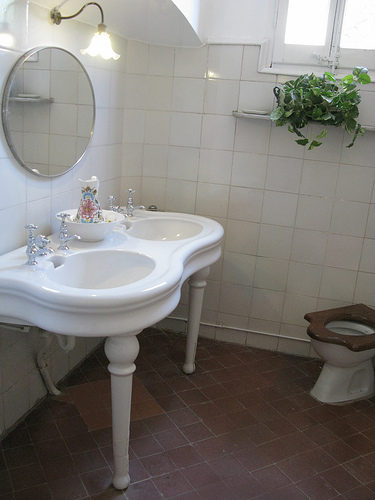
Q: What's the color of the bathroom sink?
A: White.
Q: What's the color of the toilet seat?
A: Brown.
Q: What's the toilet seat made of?
A: Wood.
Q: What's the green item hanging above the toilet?
A: Plant.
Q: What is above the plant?
A: Window.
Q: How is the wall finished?
A: Tile.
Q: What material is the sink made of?
A: Porcelain.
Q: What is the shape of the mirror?
A: Round.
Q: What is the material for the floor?
A: Brick.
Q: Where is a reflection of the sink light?
A: Left of sink light.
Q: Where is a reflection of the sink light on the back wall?
A: Left of the plant.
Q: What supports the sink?
A: Two legs.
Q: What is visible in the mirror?
A: Plant shelf.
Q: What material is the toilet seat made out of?
A: Wood.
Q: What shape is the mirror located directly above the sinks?
A: Circle.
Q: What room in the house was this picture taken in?
A: The bathroom.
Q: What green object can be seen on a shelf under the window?
A: A plant.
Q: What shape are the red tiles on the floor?
A: Square.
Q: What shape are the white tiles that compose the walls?
A: Square.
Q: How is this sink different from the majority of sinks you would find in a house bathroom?
A: There are two of them.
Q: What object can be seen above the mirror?
A: A light.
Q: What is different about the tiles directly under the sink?
A: They are a different color than the rest.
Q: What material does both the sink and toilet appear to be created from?
A: Porcelain.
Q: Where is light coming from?
A: A window.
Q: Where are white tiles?
A: On the wall.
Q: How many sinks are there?
A: Two.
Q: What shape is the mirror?
A: Round.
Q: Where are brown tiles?
A: On the floor.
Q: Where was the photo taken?
A: In a bathroom.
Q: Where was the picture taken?
A: At the entrance.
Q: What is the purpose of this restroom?
A: To wash hands or pee and poop.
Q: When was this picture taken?
A: In the morning or afternoon.